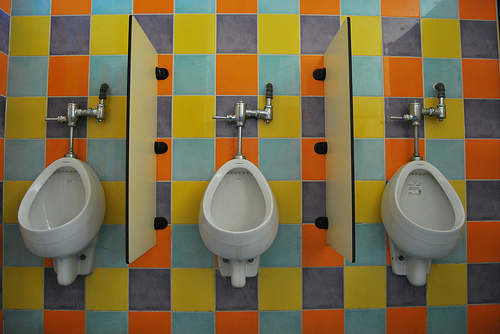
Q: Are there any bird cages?
A: No, there are no bird cages.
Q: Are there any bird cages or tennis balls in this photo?
A: No, there are no bird cages or tennis balls.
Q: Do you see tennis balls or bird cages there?
A: No, there are no bird cages or tennis balls.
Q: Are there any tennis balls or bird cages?
A: No, there are no bird cages or tennis balls.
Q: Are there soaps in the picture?
A: No, there are no soaps.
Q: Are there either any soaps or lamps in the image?
A: No, there are no soaps or lamps.